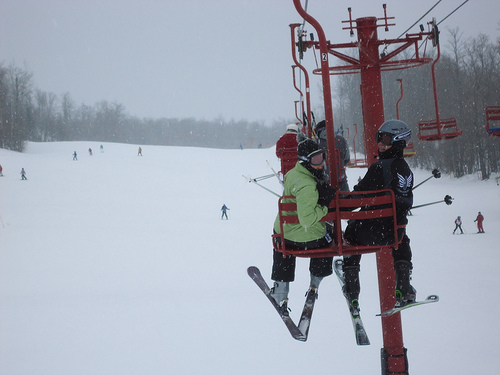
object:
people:
[270, 138, 332, 303]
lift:
[272, 187, 406, 261]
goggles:
[376, 132, 406, 145]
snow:
[0, 138, 500, 375]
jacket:
[272, 162, 331, 242]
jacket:
[331, 148, 415, 247]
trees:
[0, 59, 33, 152]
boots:
[390, 257, 418, 309]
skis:
[331, 255, 373, 347]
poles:
[412, 199, 446, 210]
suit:
[276, 136, 300, 179]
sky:
[0, 0, 500, 133]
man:
[332, 118, 417, 316]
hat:
[285, 123, 303, 134]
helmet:
[378, 118, 414, 144]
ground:
[0, 142, 500, 375]